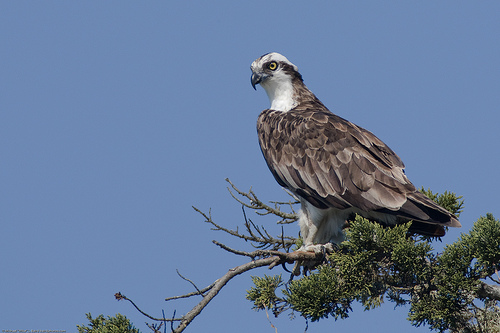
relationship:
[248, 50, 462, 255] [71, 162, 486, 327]
bird in a tree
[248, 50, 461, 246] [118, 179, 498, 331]
bird standing on branch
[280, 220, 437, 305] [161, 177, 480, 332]
green leaves on branch